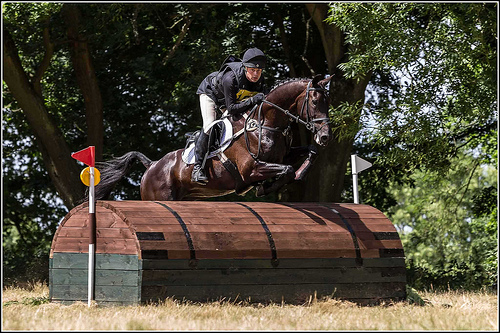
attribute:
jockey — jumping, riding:
[189, 44, 269, 186]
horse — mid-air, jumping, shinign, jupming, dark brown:
[77, 72, 334, 206]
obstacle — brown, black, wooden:
[45, 196, 412, 308]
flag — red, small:
[70, 143, 97, 166]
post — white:
[88, 168, 99, 309]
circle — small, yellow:
[79, 165, 101, 187]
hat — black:
[242, 46, 268, 71]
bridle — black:
[243, 96, 311, 162]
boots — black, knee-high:
[192, 129, 213, 188]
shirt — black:
[195, 53, 269, 117]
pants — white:
[198, 93, 217, 137]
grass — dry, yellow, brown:
[2, 275, 499, 331]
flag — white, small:
[351, 152, 373, 175]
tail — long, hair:
[73, 147, 154, 206]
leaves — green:
[1, 2, 497, 290]